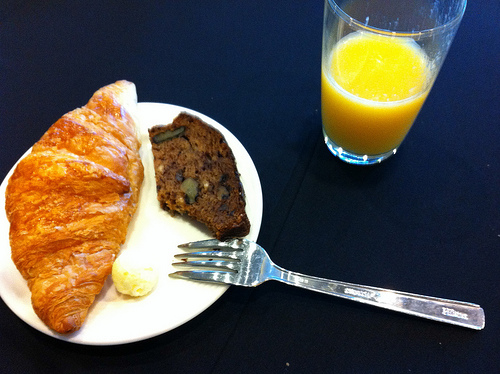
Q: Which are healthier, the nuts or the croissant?
A: The nuts are healthier than the croissant.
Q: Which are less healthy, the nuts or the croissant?
A: The croissant are less healthy than the nuts.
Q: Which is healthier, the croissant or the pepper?
A: The pepper is healthier than the croissant.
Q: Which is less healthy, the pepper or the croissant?
A: The croissant is less healthy than the pepper.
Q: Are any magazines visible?
A: No, there are no magazines.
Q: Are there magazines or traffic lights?
A: No, there are no magazines or traffic lights.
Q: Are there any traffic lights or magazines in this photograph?
A: No, there are no magazines or traffic lights.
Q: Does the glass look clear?
A: Yes, the glass is clear.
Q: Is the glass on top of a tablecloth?
A: Yes, the glass is on top of a tablecloth.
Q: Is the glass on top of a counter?
A: No, the glass is on top of a tablecloth.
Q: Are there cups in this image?
A: Yes, there is a cup.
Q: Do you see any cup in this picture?
A: Yes, there is a cup.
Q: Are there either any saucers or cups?
A: Yes, there is a cup.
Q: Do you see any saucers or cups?
A: Yes, there is a cup.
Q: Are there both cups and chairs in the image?
A: No, there is a cup but no chairs.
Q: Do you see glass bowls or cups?
A: Yes, there is a glass cup.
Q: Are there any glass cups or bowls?
A: Yes, there is a glass cup.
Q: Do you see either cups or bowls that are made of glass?
A: Yes, the cup is made of glass.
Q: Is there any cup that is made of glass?
A: Yes, there is a cup that is made of glass.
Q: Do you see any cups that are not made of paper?
A: Yes, there is a cup that is made of glass.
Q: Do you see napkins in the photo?
A: No, there are no napkins.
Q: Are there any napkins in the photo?
A: No, there are no napkins.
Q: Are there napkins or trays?
A: No, there are no napkins or trays.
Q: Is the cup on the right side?
A: Yes, the cup is on the right of the image.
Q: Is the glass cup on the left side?
A: No, the cup is on the right of the image.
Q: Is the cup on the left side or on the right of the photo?
A: The cup is on the right of the image.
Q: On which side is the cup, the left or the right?
A: The cup is on the right of the image.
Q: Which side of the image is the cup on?
A: The cup is on the right of the image.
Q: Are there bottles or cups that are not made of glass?
A: No, there is a cup but it is made of glass.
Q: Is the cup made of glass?
A: Yes, the cup is made of glass.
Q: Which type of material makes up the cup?
A: The cup is made of glass.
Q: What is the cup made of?
A: The cup is made of glass.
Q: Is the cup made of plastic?
A: No, the cup is made of glass.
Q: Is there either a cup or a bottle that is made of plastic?
A: No, there is a cup but it is made of glass.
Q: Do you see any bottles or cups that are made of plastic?
A: No, there is a cup but it is made of glass.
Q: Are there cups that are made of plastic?
A: No, there is a cup but it is made of glass.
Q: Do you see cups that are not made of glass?
A: No, there is a cup but it is made of glass.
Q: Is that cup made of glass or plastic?
A: The cup is made of glass.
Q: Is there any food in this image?
A: Yes, there is food.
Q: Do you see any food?
A: Yes, there is food.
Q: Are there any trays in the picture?
A: No, there are no trays.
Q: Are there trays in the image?
A: No, there are no trays.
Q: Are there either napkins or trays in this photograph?
A: No, there are no trays or napkins.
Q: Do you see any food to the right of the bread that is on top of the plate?
A: Yes, there is food to the right of the bread.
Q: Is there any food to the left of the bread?
A: No, the food is to the right of the bread.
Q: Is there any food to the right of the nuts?
A: Yes, there is food to the right of the nuts.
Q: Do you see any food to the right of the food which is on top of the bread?
A: Yes, there is food to the right of the nuts.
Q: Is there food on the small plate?
A: Yes, there is food on the plate.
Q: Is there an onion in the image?
A: Yes, there is an onion.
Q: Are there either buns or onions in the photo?
A: Yes, there is an onion.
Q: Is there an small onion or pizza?
A: Yes, there is a small onion.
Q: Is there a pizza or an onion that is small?
A: Yes, the onion is small.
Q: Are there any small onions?
A: Yes, there is a small onion.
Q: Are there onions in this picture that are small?
A: Yes, there is an onion that is small.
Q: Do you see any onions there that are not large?
A: Yes, there is a small onion.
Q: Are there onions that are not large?
A: Yes, there is a small onion.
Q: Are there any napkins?
A: No, there are no napkins.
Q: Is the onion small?
A: Yes, the onion is small.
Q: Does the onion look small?
A: Yes, the onion is small.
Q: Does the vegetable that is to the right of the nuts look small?
A: Yes, the onion is small.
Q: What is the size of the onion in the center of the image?
A: The onion is small.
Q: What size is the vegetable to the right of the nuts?
A: The onion is small.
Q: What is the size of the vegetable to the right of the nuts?
A: The onion is small.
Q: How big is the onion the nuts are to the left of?
A: The onion is small.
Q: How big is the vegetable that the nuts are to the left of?
A: The onion is small.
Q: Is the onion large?
A: No, the onion is small.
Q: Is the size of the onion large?
A: No, the onion is small.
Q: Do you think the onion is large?
A: No, the onion is small.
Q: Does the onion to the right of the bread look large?
A: No, the onion is small.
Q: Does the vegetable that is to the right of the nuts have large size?
A: No, the onion is small.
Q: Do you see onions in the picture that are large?
A: No, there is an onion but it is small.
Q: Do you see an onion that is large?
A: No, there is an onion but it is small.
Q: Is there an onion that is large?
A: No, there is an onion but it is small.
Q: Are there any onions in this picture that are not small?
A: No, there is an onion but it is small.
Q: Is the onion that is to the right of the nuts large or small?
A: The onion is small.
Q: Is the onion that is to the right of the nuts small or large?
A: The onion is small.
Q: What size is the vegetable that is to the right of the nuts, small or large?
A: The onion is small.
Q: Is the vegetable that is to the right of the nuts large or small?
A: The onion is small.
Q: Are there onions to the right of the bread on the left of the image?
A: Yes, there is an onion to the right of the bread.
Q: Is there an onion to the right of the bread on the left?
A: Yes, there is an onion to the right of the bread.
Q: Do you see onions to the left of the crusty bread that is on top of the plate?
A: No, the onion is to the right of the bread.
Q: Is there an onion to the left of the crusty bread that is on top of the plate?
A: No, the onion is to the right of the bread.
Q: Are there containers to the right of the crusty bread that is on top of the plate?
A: No, there is an onion to the right of the bread.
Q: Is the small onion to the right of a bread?
A: Yes, the onion is to the right of a bread.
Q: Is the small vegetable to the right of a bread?
A: Yes, the onion is to the right of a bread.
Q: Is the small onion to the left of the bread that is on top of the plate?
A: No, the onion is to the right of the bread.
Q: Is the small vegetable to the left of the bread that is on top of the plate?
A: No, the onion is to the right of the bread.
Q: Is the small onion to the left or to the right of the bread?
A: The onion is to the right of the bread.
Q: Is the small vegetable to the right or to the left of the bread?
A: The onion is to the right of the bread.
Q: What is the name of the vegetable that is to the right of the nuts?
A: The vegetable is an onion.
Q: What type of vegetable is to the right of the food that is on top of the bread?
A: The vegetable is an onion.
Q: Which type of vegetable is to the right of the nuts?
A: The vegetable is an onion.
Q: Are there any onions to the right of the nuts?
A: Yes, there is an onion to the right of the nuts.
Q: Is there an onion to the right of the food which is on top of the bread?
A: Yes, there is an onion to the right of the nuts.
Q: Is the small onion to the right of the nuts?
A: Yes, the onion is to the right of the nuts.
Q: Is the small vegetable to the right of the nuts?
A: Yes, the onion is to the right of the nuts.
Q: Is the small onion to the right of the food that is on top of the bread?
A: Yes, the onion is to the right of the nuts.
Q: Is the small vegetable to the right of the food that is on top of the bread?
A: Yes, the onion is to the right of the nuts.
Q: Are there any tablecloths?
A: Yes, there is a tablecloth.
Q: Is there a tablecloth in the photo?
A: Yes, there is a tablecloth.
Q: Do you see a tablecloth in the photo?
A: Yes, there is a tablecloth.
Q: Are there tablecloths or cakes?
A: Yes, there is a tablecloth.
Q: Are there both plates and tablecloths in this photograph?
A: Yes, there are both a tablecloth and a plate.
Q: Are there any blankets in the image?
A: No, there are no blankets.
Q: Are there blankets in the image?
A: No, there are no blankets.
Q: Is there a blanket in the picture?
A: No, there are no blankets.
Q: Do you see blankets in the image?
A: No, there are no blankets.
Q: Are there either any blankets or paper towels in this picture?
A: No, there are no blankets or paper towels.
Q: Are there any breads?
A: Yes, there is a bread.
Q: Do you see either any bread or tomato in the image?
A: Yes, there is a bread.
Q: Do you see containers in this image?
A: No, there are no containers.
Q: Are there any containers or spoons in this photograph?
A: No, there are no containers or spoons.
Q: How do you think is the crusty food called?
A: The food is a bread.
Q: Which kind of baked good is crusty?
A: The baked good is a bread.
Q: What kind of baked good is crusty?
A: The baked good is a bread.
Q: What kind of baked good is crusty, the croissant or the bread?
A: The bread is crusty.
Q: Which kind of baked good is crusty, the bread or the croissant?
A: The bread is crusty.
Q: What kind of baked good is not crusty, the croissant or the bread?
A: The croissant is not crusty.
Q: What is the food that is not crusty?
A: The food is a croissant.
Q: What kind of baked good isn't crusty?
A: The baked good is a croissant.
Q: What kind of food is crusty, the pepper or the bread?
A: The bread is crusty.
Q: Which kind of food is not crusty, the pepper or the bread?
A: The pepper is not crusty.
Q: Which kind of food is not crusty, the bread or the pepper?
A: The pepper is not crusty.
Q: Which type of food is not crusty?
A: The food is a pepper.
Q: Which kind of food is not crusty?
A: The food is a pepper.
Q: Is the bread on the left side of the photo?
A: Yes, the bread is on the left of the image.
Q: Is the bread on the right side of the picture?
A: No, the bread is on the left of the image.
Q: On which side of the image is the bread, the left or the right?
A: The bread is on the left of the image.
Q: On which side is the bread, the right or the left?
A: The bread is on the left of the image.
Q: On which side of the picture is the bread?
A: The bread is on the left of the image.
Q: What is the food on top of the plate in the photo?
A: The food is a bread.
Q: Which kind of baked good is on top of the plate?
A: The food is a bread.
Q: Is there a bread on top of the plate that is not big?
A: Yes, there is a bread on top of the plate.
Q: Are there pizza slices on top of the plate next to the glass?
A: No, there is a bread on top of the plate.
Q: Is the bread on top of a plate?
A: Yes, the bread is on top of a plate.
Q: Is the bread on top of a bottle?
A: No, the bread is on top of a plate.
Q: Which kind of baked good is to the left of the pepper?
A: The food is a bread.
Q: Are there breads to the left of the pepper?
A: Yes, there is a bread to the left of the pepper.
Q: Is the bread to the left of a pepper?
A: Yes, the bread is to the left of a pepper.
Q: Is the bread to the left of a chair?
A: No, the bread is to the left of a pepper.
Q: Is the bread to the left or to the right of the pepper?
A: The bread is to the left of the pepper.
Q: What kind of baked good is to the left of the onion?
A: The food is a bread.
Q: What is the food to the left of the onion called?
A: The food is a bread.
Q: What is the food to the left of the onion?
A: The food is a bread.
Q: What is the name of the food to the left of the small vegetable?
A: The food is a bread.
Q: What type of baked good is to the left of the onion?
A: The food is a bread.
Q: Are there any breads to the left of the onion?
A: Yes, there is a bread to the left of the onion.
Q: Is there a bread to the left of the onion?
A: Yes, there is a bread to the left of the onion.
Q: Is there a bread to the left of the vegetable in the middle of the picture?
A: Yes, there is a bread to the left of the onion.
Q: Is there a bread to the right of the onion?
A: No, the bread is to the left of the onion.